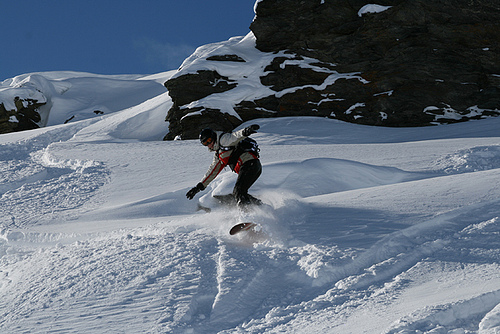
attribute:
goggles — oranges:
[198, 138, 216, 153]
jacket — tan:
[200, 128, 261, 188]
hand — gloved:
[184, 183, 207, 205]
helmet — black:
[196, 129, 217, 143]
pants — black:
[235, 165, 265, 213]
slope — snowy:
[2, 107, 482, 332]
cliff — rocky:
[150, 0, 482, 140]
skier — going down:
[173, 114, 278, 215]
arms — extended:
[175, 130, 316, 215]